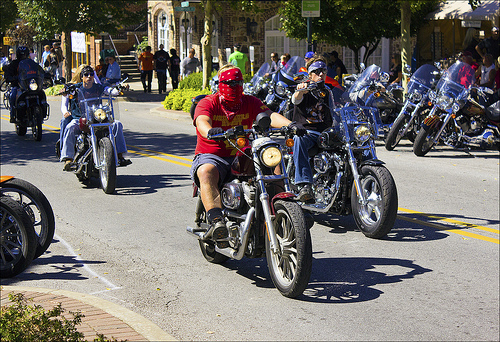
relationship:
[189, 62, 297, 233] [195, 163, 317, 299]
biker riding motorcycles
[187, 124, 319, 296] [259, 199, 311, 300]
motorcycle has wheel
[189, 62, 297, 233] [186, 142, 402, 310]
biker riding motorcycles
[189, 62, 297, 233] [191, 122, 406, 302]
biker riding motorcycles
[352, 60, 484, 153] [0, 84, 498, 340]
motorcycles parked on street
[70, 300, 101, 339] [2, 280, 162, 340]
bricks on curb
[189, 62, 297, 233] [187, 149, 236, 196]
biker wearing short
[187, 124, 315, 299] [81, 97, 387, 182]
motorcycle have headlights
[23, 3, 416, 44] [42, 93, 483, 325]
trees by street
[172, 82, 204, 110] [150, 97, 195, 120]
bushes by corner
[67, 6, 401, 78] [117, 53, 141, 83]
building has steps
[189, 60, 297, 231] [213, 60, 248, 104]
biker wearing mask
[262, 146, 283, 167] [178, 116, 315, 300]
headlight on motorcycle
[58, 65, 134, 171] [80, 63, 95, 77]
biker wearing helmet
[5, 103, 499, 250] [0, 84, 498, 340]
yellow line painted on street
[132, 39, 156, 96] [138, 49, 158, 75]
adult wearing shirt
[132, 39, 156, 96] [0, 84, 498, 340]
adult walking down street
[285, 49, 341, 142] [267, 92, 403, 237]
man riding motorcycle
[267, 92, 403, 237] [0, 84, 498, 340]
motorcycle on street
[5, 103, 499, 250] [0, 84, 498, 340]
yellow line on street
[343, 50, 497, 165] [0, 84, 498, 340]
motorcycles parked on street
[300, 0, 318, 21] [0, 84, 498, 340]
sign on street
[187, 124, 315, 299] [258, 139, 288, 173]
motorcycle has light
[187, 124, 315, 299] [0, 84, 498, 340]
motorcycle on street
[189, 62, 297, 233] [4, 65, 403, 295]
biker on motorcycles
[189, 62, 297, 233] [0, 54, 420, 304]
biker on motorcycles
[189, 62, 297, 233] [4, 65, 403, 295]
biker riding motorcycles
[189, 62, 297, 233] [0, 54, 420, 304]
biker riding motorcycles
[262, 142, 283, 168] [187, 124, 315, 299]
headlight on motorcycle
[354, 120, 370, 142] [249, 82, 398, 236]
headlight on motorcycle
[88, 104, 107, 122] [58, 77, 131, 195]
headlight on bike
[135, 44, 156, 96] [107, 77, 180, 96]
adult walking on sidewalk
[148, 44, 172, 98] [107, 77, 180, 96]
person walking on sidewalk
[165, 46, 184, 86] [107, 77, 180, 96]
person walking on sidewalk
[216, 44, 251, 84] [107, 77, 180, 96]
person walking on sidewalk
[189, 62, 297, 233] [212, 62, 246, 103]
biker wearing bandana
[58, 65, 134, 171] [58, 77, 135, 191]
biker riding bike